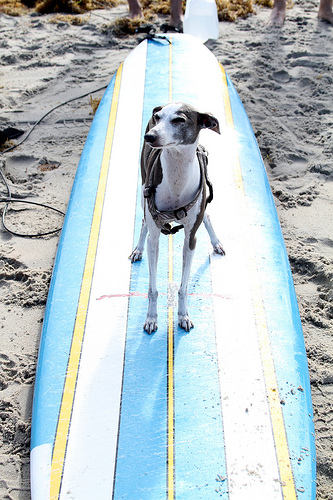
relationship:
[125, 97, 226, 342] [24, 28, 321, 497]
dog on board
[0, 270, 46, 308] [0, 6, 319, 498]
dips on sand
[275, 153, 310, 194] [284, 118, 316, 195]
dips on sand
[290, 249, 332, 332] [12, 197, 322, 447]
dips on sand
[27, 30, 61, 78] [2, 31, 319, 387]
dips on sand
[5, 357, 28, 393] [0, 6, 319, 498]
dips on sand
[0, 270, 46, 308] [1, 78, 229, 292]
dips on sand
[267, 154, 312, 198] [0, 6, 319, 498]
dips on sand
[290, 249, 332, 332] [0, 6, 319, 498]
dips on sand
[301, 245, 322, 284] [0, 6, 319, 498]
dips on sand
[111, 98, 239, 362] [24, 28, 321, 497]
dog on board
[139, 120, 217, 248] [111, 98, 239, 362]
clothing on dog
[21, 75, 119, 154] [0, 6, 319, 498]
tire tracks on sand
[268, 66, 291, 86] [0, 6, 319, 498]
footprint on sand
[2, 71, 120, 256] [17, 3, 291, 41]
cord going from trees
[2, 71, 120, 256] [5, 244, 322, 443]
cord going to beach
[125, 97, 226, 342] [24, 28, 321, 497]
dog standing on board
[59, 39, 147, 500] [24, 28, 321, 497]
stripes on board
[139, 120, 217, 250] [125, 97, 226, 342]
clothing on dog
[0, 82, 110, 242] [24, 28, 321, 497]
cord attached to board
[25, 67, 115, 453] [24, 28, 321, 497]
stripes on board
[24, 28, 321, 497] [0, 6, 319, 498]
board laying on sand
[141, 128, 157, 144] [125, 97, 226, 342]
nose on dog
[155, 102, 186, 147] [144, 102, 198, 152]
spot on face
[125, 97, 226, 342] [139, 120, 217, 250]
dog wearing clothing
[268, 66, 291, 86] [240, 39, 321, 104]
footprint in sand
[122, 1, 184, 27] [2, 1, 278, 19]
feet standing near seaweed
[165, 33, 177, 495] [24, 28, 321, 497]
stripe on a board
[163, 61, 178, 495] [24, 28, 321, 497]
stripe on a board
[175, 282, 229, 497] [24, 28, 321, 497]
stripe on a board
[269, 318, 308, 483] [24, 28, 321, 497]
blue stripe on a board